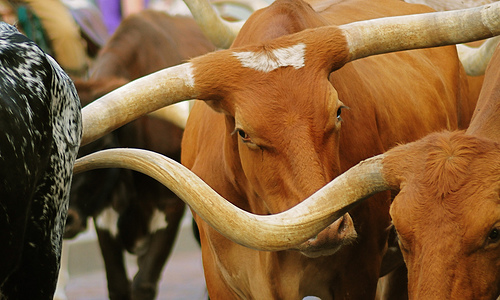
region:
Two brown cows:
[173, 46, 498, 297]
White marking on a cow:
[216, 45, 328, 82]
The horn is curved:
[95, 145, 346, 248]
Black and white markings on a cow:
[3, 28, 76, 298]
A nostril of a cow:
[334, 213, 360, 253]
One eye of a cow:
[319, 93, 346, 136]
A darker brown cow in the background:
[71, 28, 185, 298]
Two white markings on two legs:
[93, 204, 173, 245]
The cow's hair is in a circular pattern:
[421, 137, 483, 195]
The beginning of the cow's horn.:
[354, 149, 394, 191]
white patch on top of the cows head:
[234, 48, 319, 83]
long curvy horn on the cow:
[96, 133, 394, 262]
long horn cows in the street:
[80, 25, 493, 282]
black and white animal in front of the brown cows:
[4, 20, 84, 291]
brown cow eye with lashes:
[222, 123, 251, 148]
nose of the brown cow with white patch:
[301, 216, 361, 259]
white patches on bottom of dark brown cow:
[91, 206, 177, 248]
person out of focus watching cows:
[0, 5, 34, 28]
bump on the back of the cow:
[189, 5, 336, 85]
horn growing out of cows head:
[161, 48, 252, 118]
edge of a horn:
[244, 212, 273, 238]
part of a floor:
[165, 258, 185, 288]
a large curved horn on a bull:
[340, 6, 498, 48]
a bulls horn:
[64, 60, 200, 143]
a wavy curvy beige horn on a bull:
[58, 148, 390, 252]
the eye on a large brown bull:
[232, 127, 249, 142]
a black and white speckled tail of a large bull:
[0, 19, 80, 294]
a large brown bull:
[77, 3, 497, 297]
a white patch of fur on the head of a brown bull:
[232, 45, 309, 70]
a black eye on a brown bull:
[485, 220, 497, 241]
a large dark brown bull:
[60, 13, 222, 298]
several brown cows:
[41, 6, 497, 289]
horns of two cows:
[52, 10, 497, 252]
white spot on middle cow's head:
[236, 30, 301, 81]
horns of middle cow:
[55, 5, 496, 146]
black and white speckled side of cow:
[0, 23, 78, 294]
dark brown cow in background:
[60, 5, 210, 295]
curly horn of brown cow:
[72, 147, 495, 293]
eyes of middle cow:
[230, 92, 341, 147]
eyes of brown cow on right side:
[381, 216, 497, 258]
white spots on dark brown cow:
[90, 203, 163, 242]